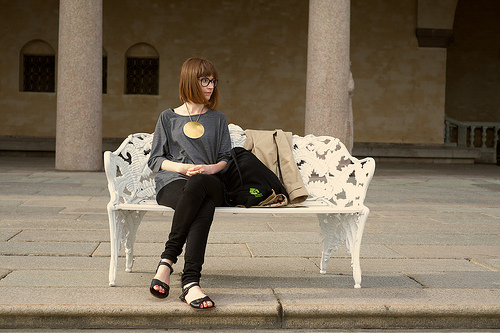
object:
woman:
[147, 54, 237, 310]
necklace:
[178, 101, 211, 140]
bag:
[220, 147, 292, 209]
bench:
[100, 122, 376, 289]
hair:
[177, 56, 219, 112]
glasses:
[196, 76, 217, 88]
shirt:
[147, 107, 233, 204]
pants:
[154, 171, 230, 288]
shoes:
[176, 279, 215, 311]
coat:
[241, 129, 309, 207]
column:
[53, 1, 109, 174]